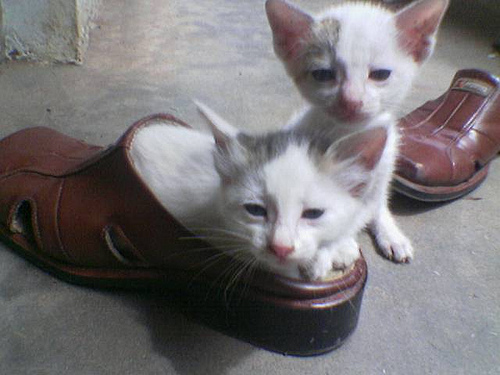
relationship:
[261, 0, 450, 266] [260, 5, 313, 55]
cat with ear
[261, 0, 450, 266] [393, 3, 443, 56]
cat with ear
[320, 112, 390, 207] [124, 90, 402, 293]
ear on kitten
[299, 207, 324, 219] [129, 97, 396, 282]
eye on kitten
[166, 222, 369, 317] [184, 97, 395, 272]
whiskers on face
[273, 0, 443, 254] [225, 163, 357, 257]
cat has face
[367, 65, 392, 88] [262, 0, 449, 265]
left eye of cat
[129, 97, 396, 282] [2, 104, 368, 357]
kitten sitting in brown shoe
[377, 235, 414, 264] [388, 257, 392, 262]
paw with nail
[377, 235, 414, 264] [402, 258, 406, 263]
paw with nail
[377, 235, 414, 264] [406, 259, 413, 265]
paw with nail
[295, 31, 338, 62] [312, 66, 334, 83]
fur above eye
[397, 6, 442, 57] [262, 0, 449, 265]
ear on cat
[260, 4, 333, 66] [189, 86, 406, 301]
ear on cat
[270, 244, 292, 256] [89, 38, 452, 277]
nose on cat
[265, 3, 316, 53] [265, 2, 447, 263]
ear on kitten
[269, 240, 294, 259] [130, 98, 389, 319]
nose on cat